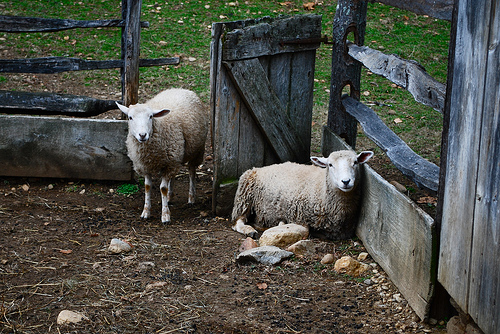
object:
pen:
[1, 1, 182, 181]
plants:
[115, 183, 138, 195]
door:
[210, 14, 319, 187]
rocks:
[108, 237, 132, 254]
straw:
[100, 296, 121, 303]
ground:
[0, 114, 168, 178]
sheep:
[115, 87, 209, 226]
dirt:
[0, 181, 450, 333]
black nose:
[340, 179, 351, 188]